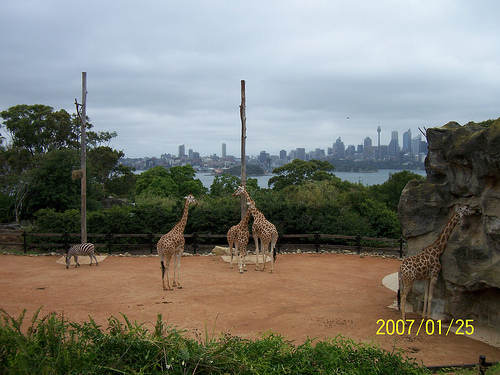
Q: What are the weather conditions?
A: It is cloudy.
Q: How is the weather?
A: It is cloudy.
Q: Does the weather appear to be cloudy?
A: Yes, it is cloudy.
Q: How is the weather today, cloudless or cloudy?
A: It is cloudy.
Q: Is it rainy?
A: No, it is cloudy.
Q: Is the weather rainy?
A: No, it is cloudy.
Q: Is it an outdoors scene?
A: Yes, it is outdoors.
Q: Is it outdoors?
A: Yes, it is outdoors.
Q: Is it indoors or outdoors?
A: It is outdoors.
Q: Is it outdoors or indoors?
A: It is outdoors.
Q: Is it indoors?
A: No, it is outdoors.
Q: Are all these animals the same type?
A: No, there are both giraffes and zebras.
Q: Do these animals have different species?
A: Yes, they are giraffes and zebras.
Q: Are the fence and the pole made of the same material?
A: Yes, both the fence and the pole are made of wood.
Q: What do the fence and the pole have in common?
A: The material, both the fence and the pole are wooden.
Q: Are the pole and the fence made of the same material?
A: Yes, both the pole and the fence are made of wood.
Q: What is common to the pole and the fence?
A: The material, both the pole and the fence are wooden.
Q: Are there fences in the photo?
A: Yes, there is a fence.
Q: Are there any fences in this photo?
A: Yes, there is a fence.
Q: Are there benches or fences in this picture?
A: Yes, there is a fence.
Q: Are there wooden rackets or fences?
A: Yes, there is a wood fence.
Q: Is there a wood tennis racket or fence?
A: Yes, there is a wood fence.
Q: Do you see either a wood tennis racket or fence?
A: Yes, there is a wood fence.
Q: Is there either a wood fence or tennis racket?
A: Yes, there is a wood fence.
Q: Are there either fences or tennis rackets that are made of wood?
A: Yes, the fence is made of wood.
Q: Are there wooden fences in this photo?
A: Yes, there is a wood fence.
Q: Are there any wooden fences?
A: Yes, there is a wood fence.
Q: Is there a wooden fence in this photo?
A: Yes, there is a wood fence.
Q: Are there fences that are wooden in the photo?
A: Yes, there is a wood fence.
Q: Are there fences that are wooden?
A: Yes, there is a fence that is wooden.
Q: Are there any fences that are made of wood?
A: Yes, there is a fence that is made of wood.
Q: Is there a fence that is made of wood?
A: Yes, there is a fence that is made of wood.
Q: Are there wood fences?
A: Yes, there is a fence that is made of wood.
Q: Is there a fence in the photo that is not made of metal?
A: Yes, there is a fence that is made of wood.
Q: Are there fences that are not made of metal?
A: Yes, there is a fence that is made of wood.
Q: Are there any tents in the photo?
A: No, there are no tents.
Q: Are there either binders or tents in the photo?
A: No, there are no tents or binders.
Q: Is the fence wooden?
A: Yes, the fence is wooden.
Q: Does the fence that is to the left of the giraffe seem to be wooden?
A: Yes, the fence is wooden.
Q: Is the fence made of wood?
A: Yes, the fence is made of wood.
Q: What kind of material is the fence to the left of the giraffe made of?
A: The fence is made of wood.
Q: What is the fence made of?
A: The fence is made of wood.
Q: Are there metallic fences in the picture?
A: No, there is a fence but it is wooden.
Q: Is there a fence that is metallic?
A: No, there is a fence but it is wooden.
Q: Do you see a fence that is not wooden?
A: No, there is a fence but it is wooden.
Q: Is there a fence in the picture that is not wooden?
A: No, there is a fence but it is wooden.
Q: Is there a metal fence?
A: No, there is a fence but it is made of wood.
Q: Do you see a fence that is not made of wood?
A: No, there is a fence but it is made of wood.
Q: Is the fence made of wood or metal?
A: The fence is made of wood.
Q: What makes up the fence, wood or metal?
A: The fence is made of wood.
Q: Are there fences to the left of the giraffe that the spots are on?
A: Yes, there is a fence to the left of the giraffe.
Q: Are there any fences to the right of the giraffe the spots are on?
A: No, the fence is to the left of the giraffe.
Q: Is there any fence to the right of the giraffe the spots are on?
A: No, the fence is to the left of the giraffe.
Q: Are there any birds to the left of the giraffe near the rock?
A: No, there is a fence to the left of the giraffe.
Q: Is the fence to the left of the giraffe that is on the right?
A: Yes, the fence is to the left of the giraffe.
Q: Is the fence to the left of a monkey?
A: No, the fence is to the left of the giraffe.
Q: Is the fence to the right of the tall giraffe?
A: No, the fence is to the left of the giraffe.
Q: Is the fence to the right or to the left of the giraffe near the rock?
A: The fence is to the left of the giraffe.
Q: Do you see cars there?
A: No, there are no cars.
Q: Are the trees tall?
A: Yes, the trees are tall.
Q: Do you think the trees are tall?
A: Yes, the trees are tall.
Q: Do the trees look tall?
A: Yes, the trees are tall.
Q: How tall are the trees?
A: The trees are tall.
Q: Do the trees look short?
A: No, the trees are tall.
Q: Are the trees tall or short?
A: The trees are tall.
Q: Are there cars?
A: No, there are no cars.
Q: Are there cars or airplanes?
A: No, there are no cars or airplanes.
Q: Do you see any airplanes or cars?
A: No, there are no cars or airplanes.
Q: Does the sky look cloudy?
A: Yes, the sky is cloudy.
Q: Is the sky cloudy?
A: Yes, the sky is cloudy.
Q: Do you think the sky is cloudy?
A: Yes, the sky is cloudy.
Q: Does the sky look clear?
A: No, the sky is cloudy.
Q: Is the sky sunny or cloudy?
A: The sky is cloudy.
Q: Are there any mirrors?
A: No, there are no mirrors.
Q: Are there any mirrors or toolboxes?
A: No, there are no mirrors or toolboxes.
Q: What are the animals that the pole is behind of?
A: The animals are giraffes.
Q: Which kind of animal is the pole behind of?
A: The pole is behind the giraffes.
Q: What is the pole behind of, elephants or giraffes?
A: The pole is behind giraffes.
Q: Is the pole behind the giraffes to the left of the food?
A: Yes, the pole is behind the giraffes.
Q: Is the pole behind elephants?
A: No, the pole is behind the giraffes.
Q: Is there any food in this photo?
A: Yes, there is food.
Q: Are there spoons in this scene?
A: No, there are no spoons.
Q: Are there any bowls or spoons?
A: No, there are no spoons or bowls.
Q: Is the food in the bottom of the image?
A: Yes, the food is in the bottom of the image.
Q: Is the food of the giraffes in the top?
A: No, the food is in the bottom of the image.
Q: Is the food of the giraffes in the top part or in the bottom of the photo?
A: The food is in the bottom of the image.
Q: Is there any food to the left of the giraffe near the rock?
A: Yes, there is food to the left of the giraffe.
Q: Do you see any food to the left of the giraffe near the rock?
A: Yes, there is food to the left of the giraffe.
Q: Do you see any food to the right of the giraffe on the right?
A: No, the food is to the left of the giraffe.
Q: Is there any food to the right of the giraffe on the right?
A: No, the food is to the left of the giraffe.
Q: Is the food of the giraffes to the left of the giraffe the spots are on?
A: Yes, the food is to the left of the giraffe.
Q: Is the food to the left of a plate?
A: No, the food is to the left of the giraffe.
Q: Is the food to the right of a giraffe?
A: No, the food is to the left of a giraffe.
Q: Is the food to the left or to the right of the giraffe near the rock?
A: The food is to the left of the giraffe.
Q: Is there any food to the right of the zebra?
A: Yes, there is food to the right of the zebra.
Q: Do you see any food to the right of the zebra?
A: Yes, there is food to the right of the zebra.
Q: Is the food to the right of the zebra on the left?
A: Yes, the food is to the right of the zebra.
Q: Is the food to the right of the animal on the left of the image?
A: Yes, the food is to the right of the zebra.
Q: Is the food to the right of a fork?
A: No, the food is to the right of the zebra.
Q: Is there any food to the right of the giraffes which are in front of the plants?
A: Yes, there is food to the right of the giraffes.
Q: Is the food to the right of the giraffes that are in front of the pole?
A: Yes, the food is to the right of the giraffes.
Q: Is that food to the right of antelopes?
A: No, the food is to the right of the giraffes.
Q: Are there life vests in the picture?
A: No, there are no life vests.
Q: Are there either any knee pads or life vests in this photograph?
A: No, there are no life vests or knee pads.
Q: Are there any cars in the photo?
A: No, there are no cars.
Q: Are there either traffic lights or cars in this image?
A: No, there are no cars or traffic lights.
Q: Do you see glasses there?
A: No, there are no glasses.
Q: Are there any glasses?
A: No, there are no glasses.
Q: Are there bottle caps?
A: No, there are no bottle caps.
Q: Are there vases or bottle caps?
A: No, there are no bottle caps or vases.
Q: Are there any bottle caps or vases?
A: No, there are no bottle caps or vases.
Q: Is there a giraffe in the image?
A: Yes, there is a giraffe.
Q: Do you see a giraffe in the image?
A: Yes, there is a giraffe.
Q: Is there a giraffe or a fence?
A: Yes, there is a giraffe.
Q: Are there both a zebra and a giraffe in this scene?
A: Yes, there are both a giraffe and a zebra.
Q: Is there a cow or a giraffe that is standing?
A: Yes, the giraffe is standing.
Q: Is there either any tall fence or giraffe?
A: Yes, there is a tall giraffe.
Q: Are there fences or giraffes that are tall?
A: Yes, the giraffe is tall.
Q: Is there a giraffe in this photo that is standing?
A: Yes, there is a giraffe that is standing.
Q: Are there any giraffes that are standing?
A: Yes, there is a giraffe that is standing.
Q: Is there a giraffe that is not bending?
A: Yes, there is a giraffe that is standing.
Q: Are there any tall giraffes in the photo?
A: Yes, there is a tall giraffe.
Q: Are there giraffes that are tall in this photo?
A: Yes, there is a tall giraffe.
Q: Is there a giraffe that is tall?
A: Yes, there is a giraffe that is tall.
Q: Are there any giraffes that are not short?
A: Yes, there is a tall giraffe.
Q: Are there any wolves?
A: No, there are no wolves.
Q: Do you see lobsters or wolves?
A: No, there are no wolves or lobsters.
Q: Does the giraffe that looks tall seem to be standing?
A: Yes, the giraffe is standing.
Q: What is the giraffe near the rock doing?
A: The giraffe is standing.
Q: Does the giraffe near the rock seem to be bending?
A: No, the giraffe is standing.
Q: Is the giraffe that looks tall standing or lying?
A: The giraffe is standing.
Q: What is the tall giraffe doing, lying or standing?
A: The giraffe is standing.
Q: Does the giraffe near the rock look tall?
A: Yes, the giraffe is tall.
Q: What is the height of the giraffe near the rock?
A: The giraffe is tall.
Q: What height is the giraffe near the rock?
A: The giraffe is tall.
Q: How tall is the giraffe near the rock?
A: The giraffe is tall.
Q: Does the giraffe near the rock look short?
A: No, the giraffe is tall.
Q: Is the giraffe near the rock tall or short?
A: The giraffe is tall.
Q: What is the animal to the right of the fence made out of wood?
A: The animal is a giraffe.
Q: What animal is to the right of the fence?
A: The animal is a giraffe.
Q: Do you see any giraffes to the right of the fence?
A: Yes, there is a giraffe to the right of the fence.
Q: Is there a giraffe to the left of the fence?
A: No, the giraffe is to the right of the fence.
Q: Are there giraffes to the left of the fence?
A: No, the giraffe is to the right of the fence.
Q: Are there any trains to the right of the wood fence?
A: No, there is a giraffe to the right of the fence.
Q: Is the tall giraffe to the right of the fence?
A: Yes, the giraffe is to the right of the fence.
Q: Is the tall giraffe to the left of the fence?
A: No, the giraffe is to the right of the fence.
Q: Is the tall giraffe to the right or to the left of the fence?
A: The giraffe is to the right of the fence.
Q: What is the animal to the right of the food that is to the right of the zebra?
A: The animal is a giraffe.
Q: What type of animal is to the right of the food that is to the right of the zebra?
A: The animal is a giraffe.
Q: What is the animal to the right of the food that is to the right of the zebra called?
A: The animal is a giraffe.